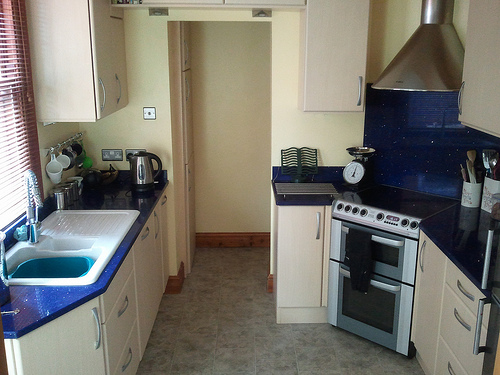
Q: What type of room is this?
A: It is a kitchen.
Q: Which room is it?
A: It is a kitchen.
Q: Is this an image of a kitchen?
A: Yes, it is showing a kitchen.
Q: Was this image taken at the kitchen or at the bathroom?
A: It was taken at the kitchen.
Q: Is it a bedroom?
A: No, it is a kitchen.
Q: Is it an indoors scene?
A: Yes, it is indoors.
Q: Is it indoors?
A: Yes, it is indoors.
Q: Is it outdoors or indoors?
A: It is indoors.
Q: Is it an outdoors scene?
A: No, it is indoors.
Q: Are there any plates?
A: No, there are no plates.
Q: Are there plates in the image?
A: No, there are no plates.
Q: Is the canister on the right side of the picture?
A: Yes, the canister is on the right of the image.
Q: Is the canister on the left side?
A: No, the canister is on the right of the image.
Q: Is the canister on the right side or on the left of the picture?
A: The canister is on the right of the image.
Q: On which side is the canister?
A: The canister is on the right of the image.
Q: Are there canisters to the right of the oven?
A: Yes, there is a canister to the right of the oven.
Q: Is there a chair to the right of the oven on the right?
A: No, there is a canister to the right of the oven.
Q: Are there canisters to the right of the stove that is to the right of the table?
A: Yes, there is a canister to the right of the stove.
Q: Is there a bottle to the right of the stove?
A: No, there is a canister to the right of the stove.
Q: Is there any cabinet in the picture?
A: Yes, there is a cabinet.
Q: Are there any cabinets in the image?
A: Yes, there is a cabinet.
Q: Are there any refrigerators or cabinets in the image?
A: Yes, there is a cabinet.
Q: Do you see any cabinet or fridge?
A: Yes, there is a cabinet.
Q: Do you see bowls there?
A: No, there are no bowls.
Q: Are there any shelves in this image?
A: No, there are no shelves.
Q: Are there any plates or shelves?
A: No, there are no shelves or plates.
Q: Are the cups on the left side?
A: Yes, the cups are on the left of the image.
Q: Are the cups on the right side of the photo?
A: No, the cups are on the left of the image.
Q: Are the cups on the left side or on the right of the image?
A: The cups are on the left of the image.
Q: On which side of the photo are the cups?
A: The cups are on the left of the image.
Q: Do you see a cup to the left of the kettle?
A: Yes, there are cups to the left of the kettle.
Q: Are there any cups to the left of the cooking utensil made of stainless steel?
A: Yes, there are cups to the left of the kettle.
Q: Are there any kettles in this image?
A: Yes, there is a kettle.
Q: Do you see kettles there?
A: Yes, there is a kettle.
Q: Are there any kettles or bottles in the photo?
A: Yes, there is a kettle.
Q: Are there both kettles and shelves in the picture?
A: No, there is a kettle but no shelves.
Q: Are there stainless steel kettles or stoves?
A: Yes, there is a stainless steel kettle.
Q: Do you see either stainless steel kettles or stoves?
A: Yes, there is a stainless steel kettle.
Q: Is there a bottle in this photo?
A: No, there are no bottles.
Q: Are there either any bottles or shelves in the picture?
A: No, there are no bottles or shelves.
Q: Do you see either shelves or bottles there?
A: No, there are no bottles or shelves.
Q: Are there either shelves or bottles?
A: No, there are no bottles or shelves.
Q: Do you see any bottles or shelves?
A: No, there are no bottles or shelves.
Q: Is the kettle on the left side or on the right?
A: The kettle is on the left of the image.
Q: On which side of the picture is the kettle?
A: The kettle is on the left of the image.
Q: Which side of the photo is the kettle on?
A: The kettle is on the left of the image.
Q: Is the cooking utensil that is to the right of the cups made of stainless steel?
A: Yes, the kettle is made of stainless steel.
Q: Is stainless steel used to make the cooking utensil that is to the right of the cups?
A: Yes, the kettle is made of stainless steel.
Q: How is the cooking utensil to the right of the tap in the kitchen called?
A: The cooking utensil is a kettle.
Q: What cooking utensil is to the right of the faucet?
A: The cooking utensil is a kettle.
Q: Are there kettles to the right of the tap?
A: Yes, there is a kettle to the right of the tap.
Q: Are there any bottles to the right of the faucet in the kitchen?
A: No, there is a kettle to the right of the faucet.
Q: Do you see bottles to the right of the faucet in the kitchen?
A: No, there is a kettle to the right of the faucet.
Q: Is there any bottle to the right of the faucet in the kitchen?
A: No, there is a kettle to the right of the faucet.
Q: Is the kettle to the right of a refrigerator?
A: No, the kettle is to the right of the faucet.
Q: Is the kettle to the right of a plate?
A: No, the kettle is to the right of a cup.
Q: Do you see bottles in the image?
A: No, there are no bottles.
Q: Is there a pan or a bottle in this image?
A: No, there are no bottles or pans.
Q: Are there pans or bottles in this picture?
A: No, there are no bottles or pans.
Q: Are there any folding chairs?
A: No, there are no folding chairs.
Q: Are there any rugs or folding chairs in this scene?
A: No, there are no folding chairs or rugs.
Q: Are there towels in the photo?
A: Yes, there is a towel.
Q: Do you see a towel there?
A: Yes, there is a towel.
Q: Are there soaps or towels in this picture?
A: Yes, there is a towel.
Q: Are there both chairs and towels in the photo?
A: No, there is a towel but no chairs.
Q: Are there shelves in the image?
A: No, there are no shelves.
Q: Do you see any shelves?
A: No, there are no shelves.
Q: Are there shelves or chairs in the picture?
A: No, there are no shelves or chairs.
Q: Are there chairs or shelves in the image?
A: No, there are no shelves or chairs.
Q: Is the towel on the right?
A: Yes, the towel is on the right of the image.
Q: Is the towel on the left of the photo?
A: No, the towel is on the right of the image.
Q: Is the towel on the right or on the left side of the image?
A: The towel is on the right of the image.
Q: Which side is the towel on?
A: The towel is on the right of the image.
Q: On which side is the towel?
A: The towel is on the right of the image.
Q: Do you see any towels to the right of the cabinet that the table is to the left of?
A: Yes, there is a towel to the right of the cabinet.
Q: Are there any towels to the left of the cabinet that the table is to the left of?
A: No, the towel is to the right of the cabinet.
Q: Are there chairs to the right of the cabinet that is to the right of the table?
A: No, there is a towel to the right of the cabinet.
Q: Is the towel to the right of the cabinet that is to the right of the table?
A: Yes, the towel is to the right of the cabinet.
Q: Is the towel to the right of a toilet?
A: No, the towel is to the right of the cabinet.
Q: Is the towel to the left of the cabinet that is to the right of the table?
A: No, the towel is to the right of the cabinet.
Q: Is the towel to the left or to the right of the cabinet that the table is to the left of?
A: The towel is to the right of the cabinet.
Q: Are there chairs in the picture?
A: No, there are no chairs.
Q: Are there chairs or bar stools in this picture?
A: No, there are no chairs or bar stools.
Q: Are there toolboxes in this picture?
A: No, there are no toolboxes.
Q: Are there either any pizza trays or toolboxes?
A: No, there are no toolboxes or pizza trays.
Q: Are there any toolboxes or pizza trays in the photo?
A: No, there are no toolboxes or pizza trays.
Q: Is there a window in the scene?
A: Yes, there is a window.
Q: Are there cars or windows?
A: Yes, there is a window.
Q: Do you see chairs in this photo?
A: No, there are no chairs.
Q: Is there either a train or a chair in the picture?
A: No, there are no chairs or trains.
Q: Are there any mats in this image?
A: No, there are no mats.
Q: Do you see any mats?
A: No, there are no mats.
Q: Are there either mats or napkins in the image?
A: No, there are no mats or napkins.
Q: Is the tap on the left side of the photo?
A: Yes, the tap is on the left of the image.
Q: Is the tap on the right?
A: No, the tap is on the left of the image.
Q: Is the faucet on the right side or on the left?
A: The faucet is on the left of the image.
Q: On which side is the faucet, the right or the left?
A: The faucet is on the left of the image.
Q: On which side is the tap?
A: The tap is on the left of the image.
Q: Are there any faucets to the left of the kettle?
A: Yes, there is a faucet to the left of the kettle.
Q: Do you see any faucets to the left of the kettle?
A: Yes, there is a faucet to the left of the kettle.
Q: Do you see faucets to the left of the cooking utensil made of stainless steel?
A: Yes, there is a faucet to the left of the kettle.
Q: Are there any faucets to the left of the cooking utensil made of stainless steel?
A: Yes, there is a faucet to the left of the kettle.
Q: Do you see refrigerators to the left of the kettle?
A: No, there is a faucet to the left of the kettle.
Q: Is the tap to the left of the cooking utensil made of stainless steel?
A: Yes, the tap is to the left of the kettle.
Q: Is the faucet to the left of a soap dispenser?
A: No, the faucet is to the left of the kettle.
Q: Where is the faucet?
A: The faucet is in the kitchen.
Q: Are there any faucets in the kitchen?
A: Yes, there is a faucet in the kitchen.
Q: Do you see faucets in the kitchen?
A: Yes, there is a faucet in the kitchen.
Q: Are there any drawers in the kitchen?
A: No, there is a faucet in the kitchen.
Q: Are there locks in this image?
A: No, there are no locks.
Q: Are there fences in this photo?
A: No, there are no fences.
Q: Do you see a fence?
A: No, there are no fences.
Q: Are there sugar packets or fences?
A: No, there are no fences or sugar packets.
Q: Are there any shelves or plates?
A: No, there are no shelves or plates.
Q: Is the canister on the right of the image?
A: Yes, the canister is on the right of the image.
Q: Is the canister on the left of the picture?
A: No, the canister is on the right of the image.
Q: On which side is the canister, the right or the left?
A: The canister is on the right of the image.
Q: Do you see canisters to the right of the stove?
A: Yes, there is a canister to the right of the stove.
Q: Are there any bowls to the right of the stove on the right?
A: No, there is a canister to the right of the stove.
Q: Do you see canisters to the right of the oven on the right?
A: Yes, there is a canister to the right of the oven.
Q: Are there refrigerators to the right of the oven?
A: No, there is a canister to the right of the oven.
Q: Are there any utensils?
A: Yes, there are utensils.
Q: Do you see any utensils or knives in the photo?
A: Yes, there are utensils.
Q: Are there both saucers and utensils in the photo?
A: No, there are utensils but no saucers.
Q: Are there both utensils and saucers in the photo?
A: No, there are utensils but no saucers.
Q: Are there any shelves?
A: No, there are no shelves.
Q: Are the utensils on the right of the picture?
A: Yes, the utensils are on the right of the image.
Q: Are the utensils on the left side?
A: No, the utensils are on the right of the image.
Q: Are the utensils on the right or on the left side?
A: The utensils are on the right of the image.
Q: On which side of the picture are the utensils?
A: The utensils are on the right of the image.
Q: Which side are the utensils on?
A: The utensils are on the right of the image.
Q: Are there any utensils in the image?
A: Yes, there are utensils.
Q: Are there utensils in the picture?
A: Yes, there are utensils.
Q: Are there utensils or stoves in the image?
A: Yes, there are utensils.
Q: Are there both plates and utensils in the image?
A: No, there are utensils but no plates.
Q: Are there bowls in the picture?
A: No, there are no bowls.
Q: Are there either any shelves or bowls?
A: No, there are no bowls or shelves.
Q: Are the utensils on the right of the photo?
A: Yes, the utensils are on the right of the image.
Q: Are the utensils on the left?
A: No, the utensils are on the right of the image.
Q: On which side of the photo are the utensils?
A: The utensils are on the right of the image.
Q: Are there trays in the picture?
A: No, there are no trays.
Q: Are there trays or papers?
A: No, there are no trays or papers.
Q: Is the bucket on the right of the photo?
A: No, the bucket is on the left of the image.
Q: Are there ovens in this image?
A: Yes, there is an oven.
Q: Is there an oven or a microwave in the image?
A: Yes, there is an oven.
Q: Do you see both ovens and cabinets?
A: Yes, there are both an oven and a cabinet.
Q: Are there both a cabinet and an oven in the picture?
A: Yes, there are both an oven and a cabinet.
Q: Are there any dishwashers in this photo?
A: No, there are no dishwashers.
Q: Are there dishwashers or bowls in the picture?
A: No, there are no dishwashers or bowls.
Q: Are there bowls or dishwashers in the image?
A: No, there are no dishwashers or bowls.